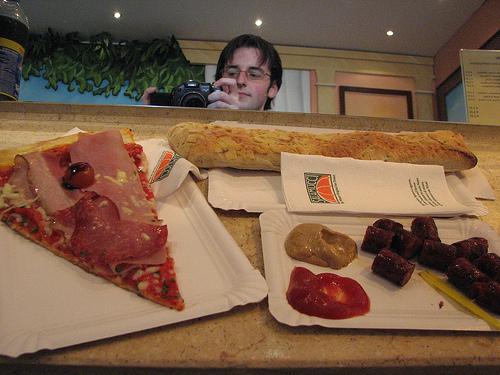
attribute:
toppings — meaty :
[20, 129, 172, 281]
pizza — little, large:
[2, 120, 189, 320]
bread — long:
[159, 118, 475, 180]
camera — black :
[145, 82, 225, 107]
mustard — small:
[282, 219, 362, 273]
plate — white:
[256, 195, 498, 337]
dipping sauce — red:
[282, 260, 372, 315]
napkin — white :
[276, 150, 460, 216]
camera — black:
[145, 77, 221, 112]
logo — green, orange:
[302, 168, 341, 207]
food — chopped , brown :
[372, 254, 419, 289]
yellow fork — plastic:
[180, 113, 461, 185]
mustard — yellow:
[278, 216, 363, 269]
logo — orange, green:
[300, 165, 341, 215]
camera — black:
[150, 85, 222, 106]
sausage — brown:
[417, 247, 484, 281]